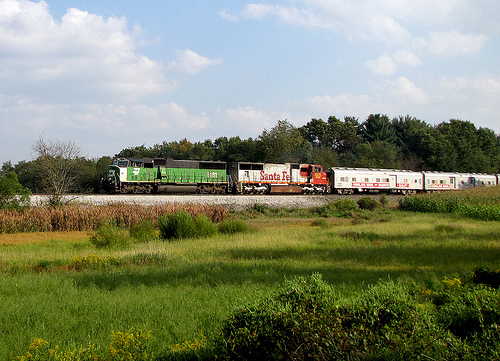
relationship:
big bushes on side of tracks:
[8, 147, 103, 242] [0, 191, 496, 218]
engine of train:
[107, 158, 230, 188] [66, 121, 489, 241]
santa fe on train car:
[257, 169, 295, 186] [254, 160, 309, 188]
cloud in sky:
[167, 47, 212, 77] [1, 0, 499, 166]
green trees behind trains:
[147, 114, 498, 169] [108, 153, 499, 193]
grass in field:
[2, 207, 494, 359] [5, 206, 497, 360]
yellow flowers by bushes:
[17, 320, 212, 359] [209, 264, 499, 359]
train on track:
[92, 150, 499, 197] [0, 190, 322, 217]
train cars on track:
[329, 160, 497, 201] [38, 186, 490, 204]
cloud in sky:
[167, 47, 212, 77] [21, 10, 492, 127]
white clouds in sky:
[352, 58, 418, 105] [3, 3, 499, 147]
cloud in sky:
[167, 47, 212, 77] [3, 3, 499, 147]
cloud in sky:
[370, 71, 434, 109] [1, 0, 499, 166]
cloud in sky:
[167, 47, 212, 77] [26, 6, 498, 174]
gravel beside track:
[8, 191, 410, 208] [6, 191, 410, 199]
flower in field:
[37, 319, 169, 359] [5, 206, 497, 360]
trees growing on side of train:
[0, 114, 499, 191] [100, 154, 500, 196]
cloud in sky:
[167, 47, 212, 77] [282, 56, 357, 90]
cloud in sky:
[167, 47, 212, 77] [0, 0, 499, 115]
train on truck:
[100, 154, 500, 196] [106, 157, 231, 193]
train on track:
[100, 154, 500, 196] [6, 184, 479, 210]